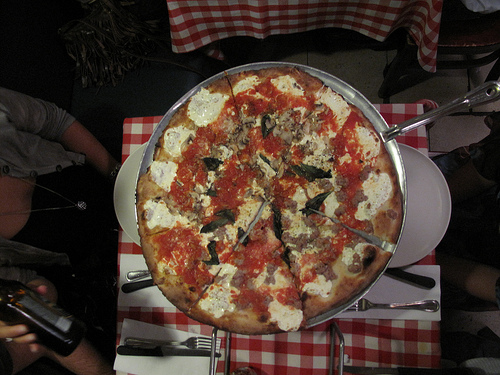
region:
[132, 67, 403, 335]
Whole pizza with cheese, sausage, and mushrooms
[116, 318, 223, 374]
Silverware on a napkin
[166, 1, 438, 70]
Red and white gingham tablecloth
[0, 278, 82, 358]
Hand holding a beer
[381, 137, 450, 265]
Empty plate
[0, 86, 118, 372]
Person sitting waiting to eat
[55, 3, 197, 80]
Handbag on bench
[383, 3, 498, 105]
Wooden chair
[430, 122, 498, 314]
Person sitting waiting to eat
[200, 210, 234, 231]
Mushrooms on pizza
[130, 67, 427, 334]
a pizza on a metal stand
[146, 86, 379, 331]
a pizza on a metal pan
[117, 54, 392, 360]
a pizza on a round pan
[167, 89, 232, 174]
melted cheese on a pizza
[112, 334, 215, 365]
a set of silverware on a table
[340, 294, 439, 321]
a fork on a white napkin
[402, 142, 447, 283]
a empty white plate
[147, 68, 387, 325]
a sliced pizza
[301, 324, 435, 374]
a red and white table cloth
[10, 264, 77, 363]
a person holding a cell phone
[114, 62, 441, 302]
The pizza has been cut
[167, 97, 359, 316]
The pizza has red sauce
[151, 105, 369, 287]
the cheese is white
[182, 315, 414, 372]
Picnic table style cloth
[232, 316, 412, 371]
the cloth is red and white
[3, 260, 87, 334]
holding a beer bottle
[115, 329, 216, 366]
the utensils are silver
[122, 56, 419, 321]
the tray is silver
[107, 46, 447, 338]
pizza sitting on a tray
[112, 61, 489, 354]
a pizza on a pan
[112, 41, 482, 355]
a large pizza on a pan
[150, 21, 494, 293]
a cooked pizz on a pan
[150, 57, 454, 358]
a bake pizza on a table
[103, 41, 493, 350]
a pizza that is sliced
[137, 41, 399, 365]
a large pizza on a table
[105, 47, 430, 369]
a baked pizza on a table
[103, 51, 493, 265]
a baked pizza sliced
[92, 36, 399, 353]
a sliced baked pizza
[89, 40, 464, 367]
red and white checker clothes